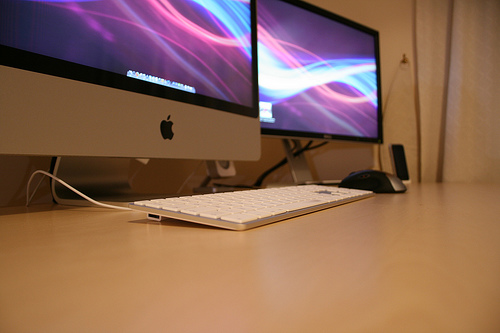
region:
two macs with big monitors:
[1, 0, 386, 170]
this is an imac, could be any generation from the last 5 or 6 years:
[1, 0, 266, 215]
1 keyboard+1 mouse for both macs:
[126, 164, 412, 241]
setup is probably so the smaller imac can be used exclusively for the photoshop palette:
[2, 1, 407, 265]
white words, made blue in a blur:
[122, 64, 200, 99]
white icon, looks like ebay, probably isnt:
[258, 96, 282, 130]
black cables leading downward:
[196, 124, 344, 204]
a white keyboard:
[130, 176, 372, 224]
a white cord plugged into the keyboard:
[22, 165, 129, 214]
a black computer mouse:
[339, 169, 406, 191]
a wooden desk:
[13, 170, 463, 297]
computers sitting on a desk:
[6, 5, 395, 187]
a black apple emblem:
[156, 110, 180, 140]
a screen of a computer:
[256, 0, 386, 137]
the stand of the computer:
[281, 139, 321, 183]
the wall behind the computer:
[384, 11, 499, 161]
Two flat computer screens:
[0, 0, 385, 164]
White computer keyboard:
[124, 180, 373, 229]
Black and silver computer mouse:
[336, 163, 406, 198]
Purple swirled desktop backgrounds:
[0, 0, 379, 139]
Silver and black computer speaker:
[385, 141, 413, 188]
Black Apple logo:
[155, 112, 178, 142]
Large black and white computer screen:
[0, 0, 262, 163]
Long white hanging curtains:
[406, 0, 496, 188]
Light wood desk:
[0, 172, 496, 327]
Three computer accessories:
[127, 140, 414, 232]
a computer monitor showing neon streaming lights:
[0, 0, 256, 160]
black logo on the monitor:
[155, 111, 175, 141]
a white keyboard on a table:
[130, 177, 370, 227]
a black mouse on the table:
[336, 166, 406, 191]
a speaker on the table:
[386, 140, 408, 185]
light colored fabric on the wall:
[411, 0, 496, 180]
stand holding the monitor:
[280, 136, 315, 181]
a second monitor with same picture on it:
[256, 0, 381, 140]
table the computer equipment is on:
[0, 181, 497, 327]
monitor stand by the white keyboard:
[50, 156, 186, 207]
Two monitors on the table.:
[48, 19, 407, 149]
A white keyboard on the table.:
[138, 179, 372, 222]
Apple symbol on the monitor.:
[152, 109, 192, 146]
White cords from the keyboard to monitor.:
[26, 155, 131, 208]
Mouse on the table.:
[350, 172, 436, 214]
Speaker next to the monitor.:
[377, 123, 424, 185]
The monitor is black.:
[251, 23, 393, 148]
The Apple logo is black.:
[147, 103, 197, 148]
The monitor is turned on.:
[64, 21, 252, 114]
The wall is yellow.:
[386, 10, 467, 137]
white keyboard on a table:
[103, 118, 386, 258]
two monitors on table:
[18, 0, 434, 155]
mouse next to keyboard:
[345, 162, 413, 211]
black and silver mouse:
[332, 168, 397, 190]